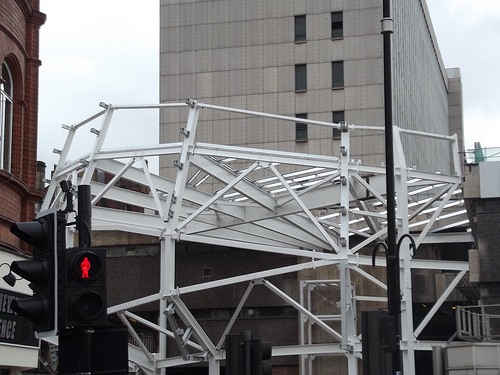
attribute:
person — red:
[64, 244, 101, 282]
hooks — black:
[360, 197, 418, 303]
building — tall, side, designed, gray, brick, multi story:
[170, 4, 323, 109]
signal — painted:
[69, 239, 128, 313]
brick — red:
[6, 25, 63, 140]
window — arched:
[2, 54, 34, 105]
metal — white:
[132, 137, 403, 281]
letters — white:
[171, 324, 259, 370]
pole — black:
[373, 25, 437, 130]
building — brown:
[0, 26, 64, 77]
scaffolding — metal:
[100, 128, 198, 243]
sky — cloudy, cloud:
[78, 30, 147, 83]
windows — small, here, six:
[260, 15, 362, 130]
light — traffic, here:
[52, 241, 142, 316]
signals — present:
[10, 224, 120, 361]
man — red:
[51, 258, 126, 301]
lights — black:
[35, 254, 60, 375]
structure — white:
[80, 122, 344, 373]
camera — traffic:
[43, 175, 92, 211]